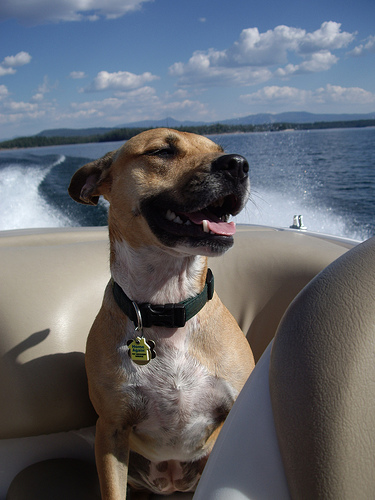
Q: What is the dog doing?
A: Enjoying a boat ride.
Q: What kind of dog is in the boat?
A: A mutt.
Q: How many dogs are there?
A: One.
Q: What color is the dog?
A: Brown.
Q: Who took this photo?
A: A tourist.